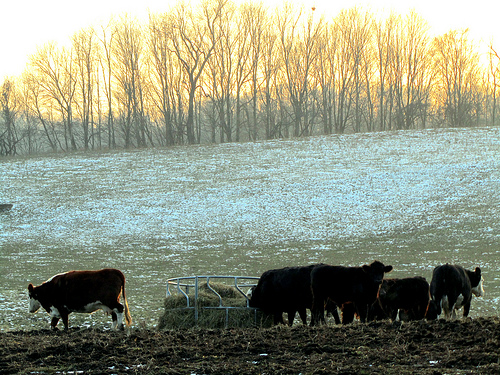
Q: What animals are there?
A: Cows.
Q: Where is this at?
A: Field.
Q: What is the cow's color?
A: Brown and white.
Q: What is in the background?
A: Trees.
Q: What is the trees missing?
A: Leaves.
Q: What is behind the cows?
A: A hill.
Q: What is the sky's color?
A: White.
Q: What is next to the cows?
A: Hay.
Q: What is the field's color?
A: White and green.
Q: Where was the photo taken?
A: In a field.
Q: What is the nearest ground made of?
A: Dirt.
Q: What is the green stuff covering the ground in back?
A: Grass.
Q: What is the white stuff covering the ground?
A: Snow.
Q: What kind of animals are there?
A: Cows.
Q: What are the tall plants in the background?
A: Trees.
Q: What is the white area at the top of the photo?
A: The sky.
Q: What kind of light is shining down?
A: Sunlight.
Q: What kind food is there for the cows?
A: Hay.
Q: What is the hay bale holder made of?
A: Metal.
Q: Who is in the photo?
A: No one.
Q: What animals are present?
A: Cows.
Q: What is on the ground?
A: Grass and snow.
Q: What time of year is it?
A: Winter.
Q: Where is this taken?
A: Close to the river.